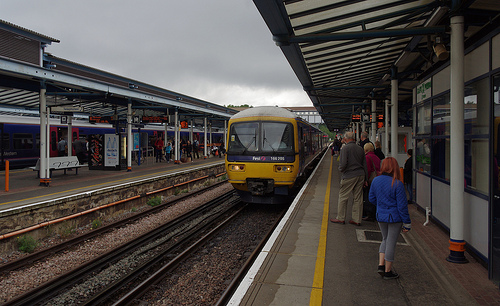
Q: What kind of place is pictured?
A: It is a station.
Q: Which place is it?
A: It is a station.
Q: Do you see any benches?
A: Yes, there is a bench.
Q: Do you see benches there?
A: Yes, there is a bench.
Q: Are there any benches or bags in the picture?
A: Yes, there is a bench.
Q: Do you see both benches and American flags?
A: No, there is a bench but no American flags.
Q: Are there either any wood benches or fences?
A: Yes, there is a wood bench.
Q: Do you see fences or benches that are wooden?
A: Yes, the bench is wooden.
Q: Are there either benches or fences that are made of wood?
A: Yes, the bench is made of wood.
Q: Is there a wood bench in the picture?
A: Yes, there is a wood bench.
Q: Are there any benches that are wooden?
A: Yes, there is a bench that is wooden.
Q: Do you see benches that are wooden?
A: Yes, there is a bench that is wooden.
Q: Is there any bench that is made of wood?
A: Yes, there is a bench that is made of wood.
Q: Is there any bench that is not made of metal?
A: Yes, there is a bench that is made of wood.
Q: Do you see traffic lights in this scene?
A: No, there are no traffic lights.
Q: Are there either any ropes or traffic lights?
A: No, there are no traffic lights or ropes.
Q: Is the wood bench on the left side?
A: Yes, the bench is on the left of the image.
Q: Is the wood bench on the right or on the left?
A: The bench is on the left of the image.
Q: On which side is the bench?
A: The bench is on the left of the image.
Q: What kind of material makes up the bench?
A: The bench is made of wood.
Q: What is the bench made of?
A: The bench is made of wood.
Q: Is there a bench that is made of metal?
A: No, there is a bench but it is made of wood.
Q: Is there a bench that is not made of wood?
A: No, there is a bench but it is made of wood.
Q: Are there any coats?
A: Yes, there is a coat.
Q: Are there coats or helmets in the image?
A: Yes, there is a coat.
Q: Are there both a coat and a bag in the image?
A: No, there is a coat but no bags.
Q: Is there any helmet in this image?
A: No, there are no helmets.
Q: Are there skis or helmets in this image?
A: No, there are no helmets or skis.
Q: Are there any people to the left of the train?
A: Yes, there are people to the left of the train.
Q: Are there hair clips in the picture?
A: No, there are no hair clips.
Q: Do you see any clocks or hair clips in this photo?
A: No, there are no hair clips or clocks.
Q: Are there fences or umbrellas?
A: No, there are no umbrellas or fences.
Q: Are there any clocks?
A: No, there are no clocks.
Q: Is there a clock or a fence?
A: No, there are no clocks or fences.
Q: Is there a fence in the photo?
A: No, there are no fences.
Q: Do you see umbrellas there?
A: No, there are no umbrellas.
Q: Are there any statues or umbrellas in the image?
A: No, there are no umbrellas or statues.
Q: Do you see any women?
A: Yes, there is a woman.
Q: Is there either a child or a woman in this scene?
A: Yes, there is a woman.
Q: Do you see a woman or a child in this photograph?
A: Yes, there is a woman.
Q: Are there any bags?
A: No, there are no bags.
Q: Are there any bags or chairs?
A: No, there are no bags or chairs.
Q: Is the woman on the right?
A: Yes, the woman is on the right of the image.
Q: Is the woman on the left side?
A: No, the woman is on the right of the image.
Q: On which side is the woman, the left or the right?
A: The woman is on the right of the image.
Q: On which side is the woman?
A: The woman is on the right of the image.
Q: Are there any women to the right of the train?
A: Yes, there is a woman to the right of the train.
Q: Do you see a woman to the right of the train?
A: Yes, there is a woman to the right of the train.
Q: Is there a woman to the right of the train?
A: Yes, there is a woman to the right of the train.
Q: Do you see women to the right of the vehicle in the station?
A: Yes, there is a woman to the right of the train.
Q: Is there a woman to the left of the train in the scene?
A: No, the woman is to the right of the train.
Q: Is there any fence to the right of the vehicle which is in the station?
A: No, there is a woman to the right of the train.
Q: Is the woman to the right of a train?
A: Yes, the woman is to the right of a train.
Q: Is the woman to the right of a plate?
A: No, the woman is to the right of a train.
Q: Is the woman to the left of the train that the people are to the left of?
A: No, the woman is to the right of the train.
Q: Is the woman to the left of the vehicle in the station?
A: No, the woman is to the right of the train.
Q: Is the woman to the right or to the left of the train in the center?
A: The woman is to the right of the train.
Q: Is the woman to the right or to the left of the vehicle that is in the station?
A: The woman is to the right of the train.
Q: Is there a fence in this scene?
A: No, there are no fences.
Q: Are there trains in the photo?
A: Yes, there is a train.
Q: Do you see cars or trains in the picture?
A: Yes, there is a train.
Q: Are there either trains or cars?
A: Yes, there is a train.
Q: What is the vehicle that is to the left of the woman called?
A: The vehicle is a train.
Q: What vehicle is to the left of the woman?
A: The vehicle is a train.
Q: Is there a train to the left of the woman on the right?
A: Yes, there is a train to the left of the woman.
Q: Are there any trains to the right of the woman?
A: No, the train is to the left of the woman.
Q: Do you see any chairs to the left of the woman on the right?
A: No, there is a train to the left of the woman.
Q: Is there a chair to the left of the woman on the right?
A: No, there is a train to the left of the woman.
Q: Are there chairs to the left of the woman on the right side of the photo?
A: No, there is a train to the left of the woman.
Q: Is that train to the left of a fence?
A: No, the train is to the left of the woman.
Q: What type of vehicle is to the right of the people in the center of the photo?
A: The vehicle is a train.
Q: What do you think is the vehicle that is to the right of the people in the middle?
A: The vehicle is a train.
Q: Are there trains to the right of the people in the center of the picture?
A: Yes, there is a train to the right of the people.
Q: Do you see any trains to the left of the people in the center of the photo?
A: No, the train is to the right of the people.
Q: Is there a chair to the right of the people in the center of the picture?
A: No, there is a train to the right of the people.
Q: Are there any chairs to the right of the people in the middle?
A: No, there is a train to the right of the people.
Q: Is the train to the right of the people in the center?
A: Yes, the train is to the right of the people.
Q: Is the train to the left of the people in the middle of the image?
A: No, the train is to the right of the people.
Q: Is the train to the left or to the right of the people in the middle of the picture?
A: The train is to the right of the people.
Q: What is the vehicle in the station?
A: The vehicle is a train.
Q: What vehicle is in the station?
A: The vehicle is a train.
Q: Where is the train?
A: The train is in the station.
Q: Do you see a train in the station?
A: Yes, there is a train in the station.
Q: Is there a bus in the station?
A: No, there is a train in the station.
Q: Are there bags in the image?
A: No, there are no bags.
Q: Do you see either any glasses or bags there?
A: No, there are no bags or glasses.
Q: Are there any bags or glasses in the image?
A: No, there are no bags or glasses.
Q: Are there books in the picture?
A: No, there are no books.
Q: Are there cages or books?
A: No, there are no books or cages.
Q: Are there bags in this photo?
A: No, there are no bags.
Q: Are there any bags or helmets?
A: No, there are no bags or helmets.